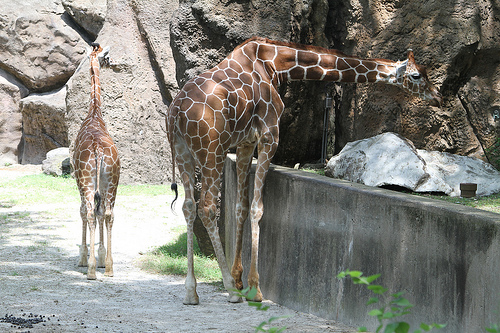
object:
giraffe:
[165, 36, 443, 304]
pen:
[2, 2, 497, 332]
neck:
[290, 50, 390, 84]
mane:
[235, 36, 395, 63]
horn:
[408, 50, 414, 63]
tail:
[167, 104, 179, 211]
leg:
[246, 135, 278, 287]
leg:
[196, 150, 235, 295]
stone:
[324, 131, 500, 198]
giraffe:
[72, 42, 121, 280]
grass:
[136, 232, 225, 292]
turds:
[0, 313, 44, 333]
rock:
[63, 1, 109, 41]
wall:
[224, 153, 500, 333]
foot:
[245, 290, 263, 302]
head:
[396, 51, 442, 108]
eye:
[411, 73, 421, 80]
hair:
[171, 183, 178, 210]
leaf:
[349, 270, 363, 277]